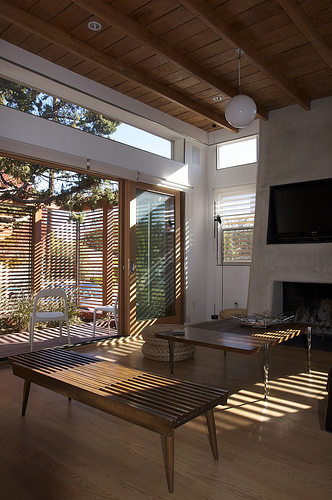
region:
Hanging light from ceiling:
[217, 93, 263, 135]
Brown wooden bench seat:
[5, 347, 240, 435]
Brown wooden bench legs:
[17, 377, 227, 495]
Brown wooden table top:
[150, 314, 316, 358]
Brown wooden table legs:
[159, 334, 317, 402]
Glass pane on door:
[132, 187, 179, 322]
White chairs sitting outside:
[25, 281, 118, 351]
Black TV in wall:
[265, 182, 330, 256]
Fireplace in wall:
[268, 274, 330, 348]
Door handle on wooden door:
[121, 257, 137, 276]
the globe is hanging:
[221, 95, 270, 125]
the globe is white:
[209, 84, 265, 134]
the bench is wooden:
[7, 346, 227, 488]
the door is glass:
[133, 194, 179, 323]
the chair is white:
[27, 284, 78, 337]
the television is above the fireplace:
[263, 193, 329, 322]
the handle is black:
[128, 254, 137, 277]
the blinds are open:
[75, 226, 106, 294]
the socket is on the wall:
[229, 298, 242, 307]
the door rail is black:
[77, 334, 112, 346]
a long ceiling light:
[221, 49, 259, 132]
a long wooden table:
[12, 344, 230, 491]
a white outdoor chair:
[21, 283, 82, 350]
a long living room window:
[0, 81, 173, 159]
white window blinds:
[210, 194, 251, 259]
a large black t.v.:
[269, 181, 329, 235]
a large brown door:
[127, 182, 184, 328]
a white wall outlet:
[230, 297, 238, 306]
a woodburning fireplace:
[271, 281, 328, 342]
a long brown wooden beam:
[0, 5, 237, 149]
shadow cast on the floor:
[61, 343, 151, 389]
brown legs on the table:
[154, 428, 194, 489]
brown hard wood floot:
[235, 438, 299, 477]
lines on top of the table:
[118, 368, 174, 405]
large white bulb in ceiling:
[212, 92, 273, 132]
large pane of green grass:
[133, 190, 181, 311]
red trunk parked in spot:
[54, 273, 110, 327]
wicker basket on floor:
[134, 326, 203, 362]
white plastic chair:
[22, 289, 76, 351]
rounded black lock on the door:
[203, 209, 235, 243]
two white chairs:
[12, 282, 136, 348]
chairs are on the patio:
[29, 276, 123, 346]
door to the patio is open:
[87, 236, 155, 331]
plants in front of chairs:
[10, 297, 35, 334]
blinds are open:
[217, 191, 259, 287]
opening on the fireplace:
[266, 283, 330, 323]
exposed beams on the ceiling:
[62, 41, 183, 88]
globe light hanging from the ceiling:
[231, 83, 275, 145]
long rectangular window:
[63, 87, 91, 132]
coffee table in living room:
[92, 364, 224, 439]